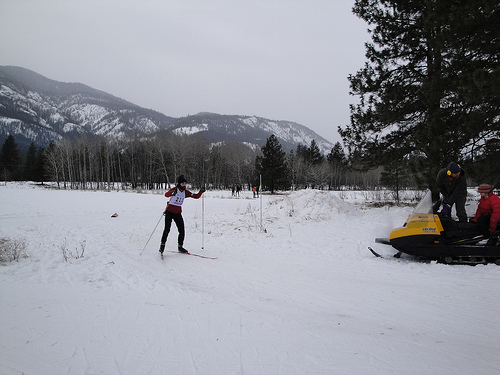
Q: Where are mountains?
A: In the distance.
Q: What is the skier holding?
A: Ski poles.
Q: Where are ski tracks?
A: On the snow.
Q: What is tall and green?
A: Pine tree.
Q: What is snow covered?
A: Mountains.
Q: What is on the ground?
A: Snow.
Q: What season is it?
A: Winter.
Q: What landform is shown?
A: Mountains.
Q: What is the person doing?
A: Skiing.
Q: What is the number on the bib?
A: 11.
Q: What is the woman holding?
A: Ski poles.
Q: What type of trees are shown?
A: Evergreens.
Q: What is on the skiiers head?
A: Hat.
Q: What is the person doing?
A: Skiing.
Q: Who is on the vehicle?
A: A man and woman.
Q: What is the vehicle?
A: A snowmobile.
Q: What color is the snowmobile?
A: Yellow.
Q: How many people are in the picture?
A: 3.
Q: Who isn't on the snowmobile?
A: The skier.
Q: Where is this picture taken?
A: The mountains.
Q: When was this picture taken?
A: Daytime.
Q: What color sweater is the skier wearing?
A: Red.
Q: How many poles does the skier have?
A: 2.